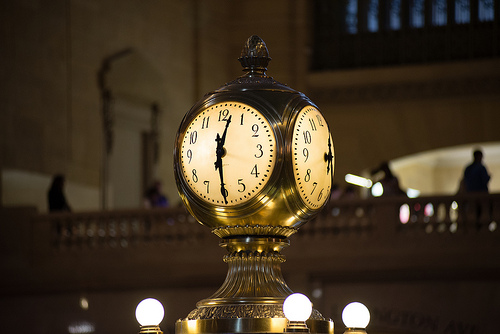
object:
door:
[104, 119, 154, 236]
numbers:
[191, 168, 199, 183]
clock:
[182, 101, 277, 208]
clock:
[291, 106, 333, 208]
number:
[250, 123, 260, 138]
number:
[216, 109, 228, 120]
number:
[318, 114, 323, 126]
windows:
[336, 5, 497, 33]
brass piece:
[237, 32, 271, 74]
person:
[40, 169, 75, 211]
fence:
[4, 190, 498, 254]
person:
[451, 142, 491, 217]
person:
[364, 158, 411, 201]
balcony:
[13, 200, 493, 280]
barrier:
[40, 200, 497, 249]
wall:
[9, 7, 144, 125]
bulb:
[354, 142, 415, 228]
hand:
[213, 113, 230, 200]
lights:
[131, 295, 168, 326]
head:
[470, 150, 484, 162]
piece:
[152, 27, 360, 243]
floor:
[12, 253, 492, 289]